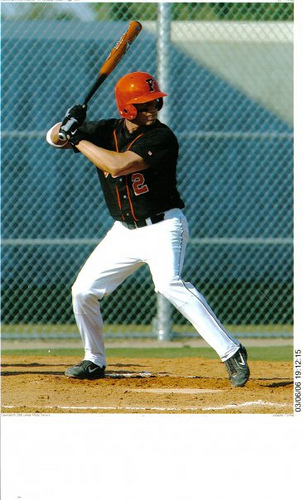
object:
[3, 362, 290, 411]
dirt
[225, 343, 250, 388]
shoe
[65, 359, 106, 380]
shoe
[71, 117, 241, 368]
uniform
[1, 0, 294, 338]
fence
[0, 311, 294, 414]
ground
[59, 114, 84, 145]
gloves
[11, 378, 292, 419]
clay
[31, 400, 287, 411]
lines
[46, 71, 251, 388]
baseball player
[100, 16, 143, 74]
rounded end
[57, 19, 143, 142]
baseball bat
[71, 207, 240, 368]
pants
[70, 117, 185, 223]
black jersey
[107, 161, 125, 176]
elbow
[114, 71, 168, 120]
helmet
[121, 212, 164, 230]
belt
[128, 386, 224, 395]
base plate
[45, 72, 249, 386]
batter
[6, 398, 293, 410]
stripe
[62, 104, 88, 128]
gloves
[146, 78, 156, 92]
letter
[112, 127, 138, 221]
stripe